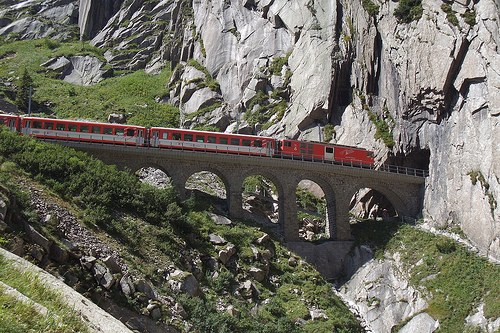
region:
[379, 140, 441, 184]
entrance to tunnel thru mountain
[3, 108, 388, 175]
red and white train on tracks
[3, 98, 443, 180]
red and white train about to enter tunnel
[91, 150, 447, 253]
bridge over gully in mountain terrain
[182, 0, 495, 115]
rocky side of mountain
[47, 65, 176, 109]
grass growing on mountain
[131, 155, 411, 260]
Arches in bridge design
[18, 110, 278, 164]
two cars from train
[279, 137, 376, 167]
first car of train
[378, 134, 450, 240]
bridge entering tunnel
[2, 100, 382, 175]
Red train moving all the tracks.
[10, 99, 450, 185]
Train about to enter the tunnel.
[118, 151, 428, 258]
Arches underneath the stone bridge.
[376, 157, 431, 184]
Metal railing alongside the train tracks.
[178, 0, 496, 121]
Steep, rocky cliffside.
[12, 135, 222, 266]
green bushes growing along the rocky cliffside.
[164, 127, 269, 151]
Windows along the passenger train car.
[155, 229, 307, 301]
Large boulders on the mountain side.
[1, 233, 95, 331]
Green grass growing from the rock.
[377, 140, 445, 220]
Bridge entering the large mountainside.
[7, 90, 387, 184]
The train is red.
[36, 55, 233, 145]
The grass is green.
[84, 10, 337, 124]
Green patches growing on the mountains.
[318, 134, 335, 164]
The train door is white.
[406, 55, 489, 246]
The stones are grey.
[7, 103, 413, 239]
Four train cars.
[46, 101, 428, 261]
One bridge going through a mountain.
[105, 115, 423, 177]
The fence is silver.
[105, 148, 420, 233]
The bridge is grey.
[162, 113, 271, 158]
The windows are black.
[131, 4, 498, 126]
a rocky mountain wall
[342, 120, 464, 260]
a tunnel going through a mountain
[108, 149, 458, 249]
a five arched railway bridge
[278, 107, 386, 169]
a red train engine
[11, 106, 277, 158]
red and white passenger cars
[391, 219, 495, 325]
a grassy area of the countryside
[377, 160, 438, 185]
Steel rails along the bridge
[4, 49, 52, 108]
a young pine tree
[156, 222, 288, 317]
Huge boulders among some grass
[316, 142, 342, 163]
wide white door to enter the engine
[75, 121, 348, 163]
the train is red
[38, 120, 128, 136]
windows on the train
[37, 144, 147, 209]
the grass is green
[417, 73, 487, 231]
the rocks are gray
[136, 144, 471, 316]
bridge is in mountains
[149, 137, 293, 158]
the rails are silver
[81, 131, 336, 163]
rails are on bridge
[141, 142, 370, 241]
arches are under bridge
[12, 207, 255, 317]
grass is on rocks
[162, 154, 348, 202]
the bridge is stone